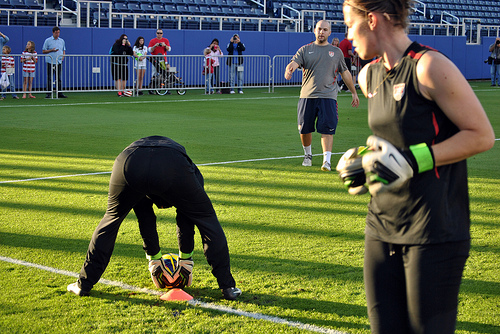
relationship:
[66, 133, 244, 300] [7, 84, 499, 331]
man standing on field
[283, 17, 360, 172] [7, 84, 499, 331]
man on field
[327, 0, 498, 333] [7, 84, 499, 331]
person standing on field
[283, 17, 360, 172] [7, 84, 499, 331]
man standing on field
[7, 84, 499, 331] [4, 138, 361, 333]
field with white lines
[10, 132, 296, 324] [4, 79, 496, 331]
white line on grass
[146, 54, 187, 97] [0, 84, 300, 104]
stroller on grass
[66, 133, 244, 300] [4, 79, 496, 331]
man standing in grass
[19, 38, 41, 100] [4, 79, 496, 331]
person standing in grass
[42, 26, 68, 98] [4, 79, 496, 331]
person standing in grass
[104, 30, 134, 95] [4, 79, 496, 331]
person standing in grass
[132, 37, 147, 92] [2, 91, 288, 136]
person standing in grass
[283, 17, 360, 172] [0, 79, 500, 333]
man standing in grass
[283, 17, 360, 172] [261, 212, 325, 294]
man standing in grass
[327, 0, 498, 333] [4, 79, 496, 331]
person standing in grass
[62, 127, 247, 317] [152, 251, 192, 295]
man holding on ball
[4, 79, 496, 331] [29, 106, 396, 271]
grass on field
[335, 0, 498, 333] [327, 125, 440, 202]
person wearing gloves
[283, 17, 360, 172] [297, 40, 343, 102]
man wearing t-shirt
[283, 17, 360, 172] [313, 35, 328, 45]
man with a beard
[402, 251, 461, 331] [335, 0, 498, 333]
leg of person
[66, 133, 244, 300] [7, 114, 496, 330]
man standing in grass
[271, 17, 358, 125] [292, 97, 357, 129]
man wearing shorts